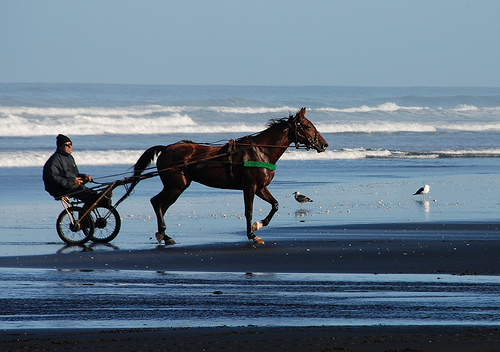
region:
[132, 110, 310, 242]
horse running on wet beach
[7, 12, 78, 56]
blu sky with no clouds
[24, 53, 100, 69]
blu sky with no clouds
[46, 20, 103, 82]
blu sky with no clouds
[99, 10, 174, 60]
blu sky with no clouds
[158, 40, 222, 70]
blu sky with no clouds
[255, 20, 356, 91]
blu sky with no clouds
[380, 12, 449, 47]
blu sky with no clouds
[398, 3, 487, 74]
blu sky with no clouds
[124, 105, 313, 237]
brown horse runing on beach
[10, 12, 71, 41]
white clouds against blue sky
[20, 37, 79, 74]
white clouds against blue sky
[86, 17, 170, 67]
white clouds against blue sky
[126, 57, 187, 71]
white clouds against blue sky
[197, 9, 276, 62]
white clouds against blue sky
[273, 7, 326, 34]
white clouds against blue sky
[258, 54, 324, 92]
white clouds against blue sky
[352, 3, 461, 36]
white clouds against blue sky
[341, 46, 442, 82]
white clouds against blue sky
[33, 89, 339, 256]
man being pulled by horse on beach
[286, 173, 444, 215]
birds on the beach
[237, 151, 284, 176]
green strap a part of horses harness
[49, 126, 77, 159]
man wearing a stocking cap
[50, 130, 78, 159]
man wearing sunglasses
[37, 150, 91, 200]
man wearing a windbreaker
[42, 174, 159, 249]
small two-wheeled carriage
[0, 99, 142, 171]
white-capped waves rolling into the beach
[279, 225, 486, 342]
dry parts of beach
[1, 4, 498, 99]
solid blue sky above ocean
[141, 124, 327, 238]
brown horse running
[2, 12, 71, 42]
white clouds in blue sky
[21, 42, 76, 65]
white clouds in blue sky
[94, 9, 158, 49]
white clouds in blue sky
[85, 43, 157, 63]
white clouds in blue sky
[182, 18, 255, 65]
white clouds in blue sky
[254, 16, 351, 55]
white clouds in blue sky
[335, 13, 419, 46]
white clouds in blue sky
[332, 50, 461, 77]
white clouds in blue sky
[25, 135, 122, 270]
man sitting on carriage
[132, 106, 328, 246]
horse walking on beach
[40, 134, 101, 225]
man wearing sunglasses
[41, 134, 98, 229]
man wearing black cap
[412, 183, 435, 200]
bird on beach facing away from the ocean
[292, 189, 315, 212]
bird facing toward the ocean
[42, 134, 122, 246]
man sitting in a carriage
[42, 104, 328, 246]
horse pulling a carriage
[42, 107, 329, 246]
man in a horse drawn carriage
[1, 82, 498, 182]
ocean in the background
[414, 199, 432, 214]
reflection of bird facing away from ocean